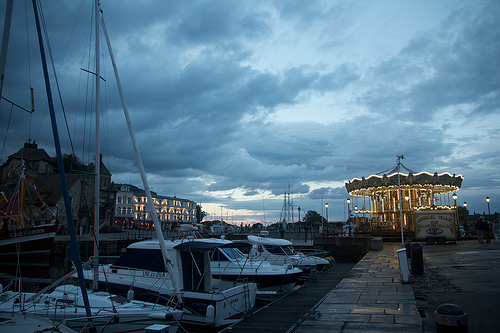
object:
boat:
[0, 281, 181, 333]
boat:
[174, 233, 330, 275]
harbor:
[1, 187, 356, 333]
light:
[179, 204, 189, 215]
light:
[172, 208, 182, 213]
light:
[165, 205, 176, 215]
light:
[134, 203, 146, 213]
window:
[265, 244, 301, 257]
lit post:
[325, 209, 329, 221]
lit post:
[399, 185, 405, 226]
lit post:
[454, 200, 457, 207]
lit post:
[487, 203, 492, 228]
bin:
[433, 302, 469, 332]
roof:
[345, 155, 462, 195]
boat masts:
[0, 0, 176, 328]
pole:
[347, 203, 349, 226]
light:
[325, 204, 329, 209]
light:
[452, 195, 457, 200]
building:
[102, 185, 202, 233]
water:
[9, 260, 79, 280]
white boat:
[236, 230, 329, 265]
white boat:
[68, 235, 256, 312]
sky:
[1, 2, 499, 232]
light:
[452, 194, 458, 200]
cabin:
[108, 238, 249, 273]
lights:
[387, 172, 442, 179]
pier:
[1, 205, 429, 330]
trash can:
[407, 241, 424, 275]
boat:
[174, 221, 303, 304]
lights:
[136, 205, 146, 211]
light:
[486, 197, 491, 203]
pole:
[486, 205, 488, 206]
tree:
[299, 209, 329, 240]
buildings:
[0, 139, 111, 230]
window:
[119, 246, 167, 271]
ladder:
[236, 278, 254, 314]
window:
[208, 247, 243, 262]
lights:
[324, 203, 328, 208]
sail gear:
[2, 3, 180, 333]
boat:
[72, 235, 259, 329]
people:
[444, 209, 499, 247]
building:
[341, 148, 467, 244]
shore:
[7, 139, 487, 282]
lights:
[172, 212, 185, 221]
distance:
[401, 205, 499, 248]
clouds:
[119, 54, 283, 176]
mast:
[3, 0, 186, 331]